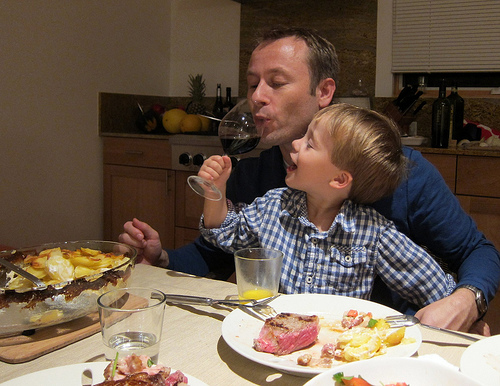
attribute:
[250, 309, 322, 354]
meat — pink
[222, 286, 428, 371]
plate — white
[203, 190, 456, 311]
shirt — checkered, blue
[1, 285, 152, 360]
plate — wood